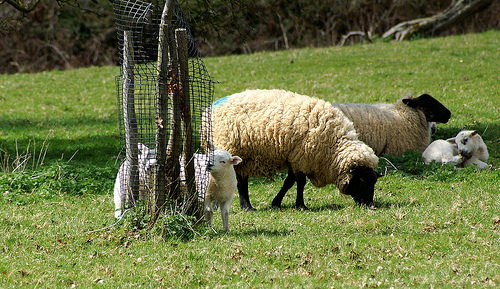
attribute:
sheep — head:
[193, 79, 385, 202]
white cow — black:
[109, 90, 491, 223]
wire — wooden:
[113, 0, 215, 235]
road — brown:
[38, 27, 450, 283]